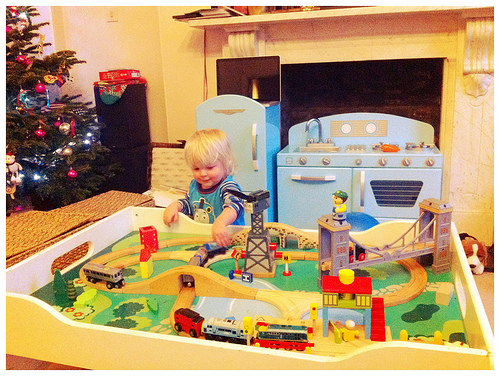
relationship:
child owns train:
[158, 124, 256, 245] [178, 236, 253, 301]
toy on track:
[166, 300, 320, 361] [82, 227, 436, 316]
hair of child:
[182, 124, 235, 177] [163, 122, 254, 257]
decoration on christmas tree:
[16, 55, 31, 64] [11, 3, 90, 188]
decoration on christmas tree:
[16, 50, 31, 69] [11, 3, 90, 188]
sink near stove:
[283, 120, 339, 152] [355, 169, 443, 216]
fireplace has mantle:
[184, 7, 491, 254] [186, 4, 492, 27]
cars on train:
[171, 304, 318, 352] [172, 307, 314, 352]